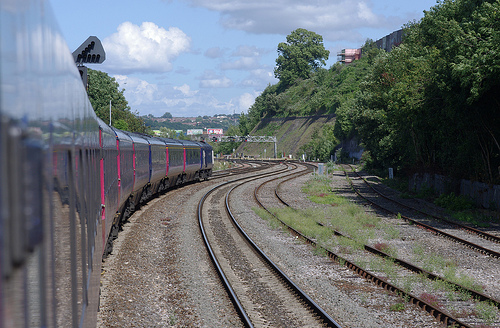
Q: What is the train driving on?
A: Tracks.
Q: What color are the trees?
A: Green.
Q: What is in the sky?
A: Clouds.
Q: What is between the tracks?
A: Gravel.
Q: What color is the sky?
A: Blue.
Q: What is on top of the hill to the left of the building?
A: A tree.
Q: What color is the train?
A: Red and silver.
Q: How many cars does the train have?
A: Eight.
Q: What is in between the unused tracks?
A: Grass.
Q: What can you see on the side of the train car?
A: A reflection.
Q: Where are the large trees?
A: Beside the railroad tracks.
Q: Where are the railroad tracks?
A: On a dirt road.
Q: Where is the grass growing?
A: On the railroad tracks.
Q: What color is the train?
A: Silver.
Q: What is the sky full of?
A: Clouds.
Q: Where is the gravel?
A: Between the tracks.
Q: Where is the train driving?
A: On the tracks.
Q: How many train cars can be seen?
A: Eight.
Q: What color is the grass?
A: Green.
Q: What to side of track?
A: Trees.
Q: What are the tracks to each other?
A: Parallel.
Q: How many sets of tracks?
A: 4.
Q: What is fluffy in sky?
A: White cloud.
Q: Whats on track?
A: Train.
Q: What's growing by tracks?
A: Trees.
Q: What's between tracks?
A: Gravel.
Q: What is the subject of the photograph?
A: Train.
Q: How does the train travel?
A: Rail tracks.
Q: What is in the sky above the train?
A: Clouds.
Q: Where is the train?
A: Westmost tracks.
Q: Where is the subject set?
A: Railroad.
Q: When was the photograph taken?
A: Daytime.